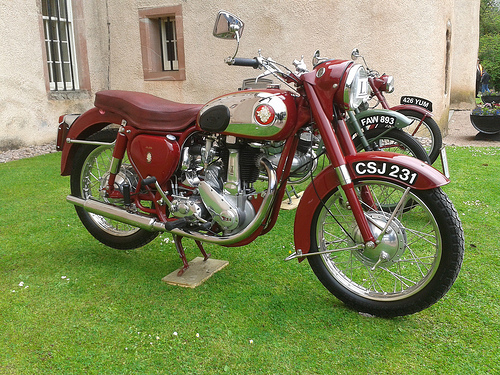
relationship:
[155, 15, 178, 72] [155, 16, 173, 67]
window covered by bars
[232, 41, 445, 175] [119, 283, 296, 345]
motorbike parked on grass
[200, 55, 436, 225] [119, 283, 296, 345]
motorbike parked on grass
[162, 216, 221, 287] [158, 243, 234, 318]
kickstand on a board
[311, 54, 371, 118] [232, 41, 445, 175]
headlamp on motorbike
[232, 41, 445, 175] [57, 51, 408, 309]
motorbike has gray fender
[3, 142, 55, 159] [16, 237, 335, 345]
gravel between lawn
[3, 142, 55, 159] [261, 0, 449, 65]
gravel between wall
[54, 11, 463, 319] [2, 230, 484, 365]
motorbike in grass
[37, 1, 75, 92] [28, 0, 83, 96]
bars on window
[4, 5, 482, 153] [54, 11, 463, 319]
building behind motorbike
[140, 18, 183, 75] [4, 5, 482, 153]
window on side building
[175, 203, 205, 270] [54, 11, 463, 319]
kickstand on motorbike